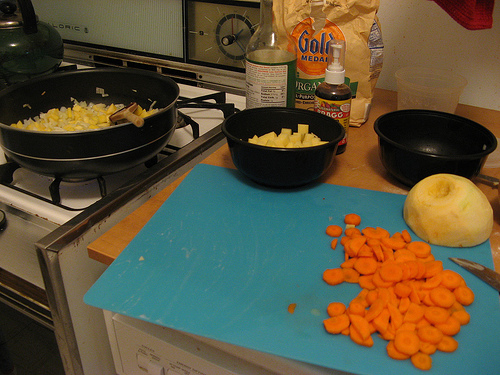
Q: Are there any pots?
A: Yes, there is a pot.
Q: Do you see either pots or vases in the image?
A: Yes, there is a pot.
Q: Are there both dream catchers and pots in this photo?
A: No, there is a pot but no dream catchers.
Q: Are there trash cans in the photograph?
A: No, there are no trash cans.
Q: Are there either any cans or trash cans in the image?
A: No, there are no trash cans or cans.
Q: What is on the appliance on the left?
A: The pot is on the gas stove.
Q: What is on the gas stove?
A: The pot is on the gas stove.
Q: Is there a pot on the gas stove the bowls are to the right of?
A: Yes, there is a pot on the gas stove.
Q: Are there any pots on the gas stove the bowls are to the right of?
A: Yes, there is a pot on the gas stove.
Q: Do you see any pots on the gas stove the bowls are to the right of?
A: Yes, there is a pot on the gas stove.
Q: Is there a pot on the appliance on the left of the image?
A: Yes, there is a pot on the gas stove.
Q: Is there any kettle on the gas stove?
A: No, there is a pot on the gas stove.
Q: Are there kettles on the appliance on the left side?
A: No, there is a pot on the gas stove.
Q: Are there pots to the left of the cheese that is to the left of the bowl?
A: Yes, there is a pot to the left of the cheese.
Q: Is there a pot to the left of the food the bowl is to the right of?
A: Yes, there is a pot to the left of the cheese.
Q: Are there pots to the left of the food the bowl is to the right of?
A: Yes, there is a pot to the left of the cheese.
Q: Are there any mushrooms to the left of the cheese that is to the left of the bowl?
A: No, there is a pot to the left of the cheese.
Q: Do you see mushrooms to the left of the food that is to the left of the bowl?
A: No, there is a pot to the left of the cheese.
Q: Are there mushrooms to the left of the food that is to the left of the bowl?
A: No, there is a pot to the left of the cheese.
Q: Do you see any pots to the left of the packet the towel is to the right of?
A: Yes, there is a pot to the left of the packet.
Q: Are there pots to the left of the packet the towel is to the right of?
A: Yes, there is a pot to the left of the packet.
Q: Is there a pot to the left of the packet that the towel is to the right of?
A: Yes, there is a pot to the left of the packet.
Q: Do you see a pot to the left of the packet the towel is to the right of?
A: Yes, there is a pot to the left of the packet.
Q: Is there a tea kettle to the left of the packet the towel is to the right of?
A: No, there is a pot to the left of the packet.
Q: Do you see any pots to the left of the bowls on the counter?
A: Yes, there is a pot to the left of the bowls.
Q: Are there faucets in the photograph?
A: No, there are no faucets.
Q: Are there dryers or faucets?
A: No, there are no faucets or dryers.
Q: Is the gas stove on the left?
A: Yes, the gas stove is on the left of the image.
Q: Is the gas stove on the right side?
A: No, the gas stove is on the left of the image.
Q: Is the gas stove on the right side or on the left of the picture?
A: The gas stove is on the left of the image.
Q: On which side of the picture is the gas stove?
A: The gas stove is on the left of the image.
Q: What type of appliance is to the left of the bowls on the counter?
A: The appliance is a gas stove.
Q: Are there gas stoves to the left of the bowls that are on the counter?
A: Yes, there is a gas stove to the left of the bowls.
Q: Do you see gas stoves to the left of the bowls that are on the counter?
A: Yes, there is a gas stove to the left of the bowls.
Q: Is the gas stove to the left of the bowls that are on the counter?
A: Yes, the gas stove is to the left of the bowls.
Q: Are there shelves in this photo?
A: No, there are no shelves.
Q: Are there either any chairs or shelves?
A: No, there are no shelves or chairs.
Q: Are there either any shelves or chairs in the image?
A: No, there are no shelves or chairs.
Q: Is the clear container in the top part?
A: Yes, the container is in the top of the image.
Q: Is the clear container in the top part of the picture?
A: Yes, the container is in the top of the image.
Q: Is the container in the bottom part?
A: No, the container is in the top of the image.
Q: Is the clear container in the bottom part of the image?
A: No, the container is in the top of the image.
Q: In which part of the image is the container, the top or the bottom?
A: The container is in the top of the image.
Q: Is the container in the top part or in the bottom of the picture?
A: The container is in the top of the image.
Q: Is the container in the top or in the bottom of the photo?
A: The container is in the top of the image.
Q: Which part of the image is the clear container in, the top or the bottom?
A: The container is in the top of the image.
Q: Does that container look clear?
A: Yes, the container is clear.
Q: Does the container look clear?
A: Yes, the container is clear.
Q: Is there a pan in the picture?
A: Yes, there is a pan.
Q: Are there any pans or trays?
A: Yes, there is a pan.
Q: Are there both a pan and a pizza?
A: No, there is a pan but no pizzas.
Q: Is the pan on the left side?
A: Yes, the pan is on the left of the image.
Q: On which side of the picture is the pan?
A: The pan is on the left of the image.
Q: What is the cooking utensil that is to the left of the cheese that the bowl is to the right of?
A: The cooking utensil is a pan.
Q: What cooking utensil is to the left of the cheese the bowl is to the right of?
A: The cooking utensil is a pan.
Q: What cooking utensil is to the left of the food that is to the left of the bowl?
A: The cooking utensil is a pan.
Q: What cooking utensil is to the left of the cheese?
A: The cooking utensil is a pan.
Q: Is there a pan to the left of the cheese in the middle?
A: Yes, there is a pan to the left of the cheese.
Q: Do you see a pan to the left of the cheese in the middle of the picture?
A: Yes, there is a pan to the left of the cheese.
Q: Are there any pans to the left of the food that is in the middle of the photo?
A: Yes, there is a pan to the left of the cheese.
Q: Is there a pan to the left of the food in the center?
A: Yes, there is a pan to the left of the cheese.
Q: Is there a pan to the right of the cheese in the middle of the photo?
A: No, the pan is to the left of the cheese.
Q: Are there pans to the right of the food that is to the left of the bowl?
A: No, the pan is to the left of the cheese.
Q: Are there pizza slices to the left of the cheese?
A: No, there is a pan to the left of the cheese.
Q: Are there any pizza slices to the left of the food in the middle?
A: No, there is a pan to the left of the cheese.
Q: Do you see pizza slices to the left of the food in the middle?
A: No, there is a pan to the left of the cheese.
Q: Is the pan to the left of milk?
A: No, the pan is to the left of the cheese.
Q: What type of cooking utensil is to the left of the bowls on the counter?
A: The cooking utensil is a pan.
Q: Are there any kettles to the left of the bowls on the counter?
A: No, there is a pan to the left of the bowls.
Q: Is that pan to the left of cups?
A: No, the pan is to the left of the bowls.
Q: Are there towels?
A: Yes, there is a towel.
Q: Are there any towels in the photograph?
A: Yes, there is a towel.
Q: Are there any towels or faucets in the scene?
A: Yes, there is a towel.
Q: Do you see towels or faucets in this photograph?
A: Yes, there is a towel.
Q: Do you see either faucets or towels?
A: Yes, there is a towel.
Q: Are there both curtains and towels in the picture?
A: No, there is a towel but no curtains.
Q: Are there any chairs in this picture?
A: No, there are no chairs.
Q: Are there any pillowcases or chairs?
A: No, there are no chairs or pillowcases.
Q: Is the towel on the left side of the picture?
A: No, the towel is on the right of the image.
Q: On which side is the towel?
A: The towel is on the right of the image.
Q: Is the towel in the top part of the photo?
A: Yes, the towel is in the top of the image.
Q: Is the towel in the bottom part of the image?
A: No, the towel is in the top of the image.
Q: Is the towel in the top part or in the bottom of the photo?
A: The towel is in the top of the image.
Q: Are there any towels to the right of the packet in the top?
A: Yes, there is a towel to the right of the packet.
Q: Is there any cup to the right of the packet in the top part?
A: No, there is a towel to the right of the packet.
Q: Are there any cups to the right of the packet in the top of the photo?
A: No, there is a towel to the right of the packet.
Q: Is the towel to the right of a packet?
A: Yes, the towel is to the right of a packet.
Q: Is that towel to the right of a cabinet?
A: No, the towel is to the right of a packet.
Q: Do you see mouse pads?
A: No, there are no mouse pads.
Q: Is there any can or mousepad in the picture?
A: No, there are no mouse pads or cans.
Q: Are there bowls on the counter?
A: Yes, there are bowls on the counter.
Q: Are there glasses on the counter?
A: No, there are bowls on the counter.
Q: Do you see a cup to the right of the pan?
A: No, there are bowls to the right of the pan.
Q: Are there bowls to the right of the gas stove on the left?
A: Yes, there are bowls to the right of the gas stove.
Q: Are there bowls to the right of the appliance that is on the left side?
A: Yes, there are bowls to the right of the gas stove.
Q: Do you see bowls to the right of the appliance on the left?
A: Yes, there are bowls to the right of the gas stove.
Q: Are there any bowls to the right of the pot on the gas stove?
A: Yes, there are bowls to the right of the pot.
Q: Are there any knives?
A: Yes, there is a knife.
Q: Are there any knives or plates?
A: Yes, there is a knife.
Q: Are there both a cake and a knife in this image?
A: No, there is a knife but no cakes.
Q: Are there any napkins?
A: No, there are no napkins.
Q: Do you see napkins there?
A: No, there are no napkins.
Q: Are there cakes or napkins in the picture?
A: No, there are no napkins or cakes.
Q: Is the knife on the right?
A: Yes, the knife is on the right of the image.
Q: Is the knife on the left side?
A: No, the knife is on the right of the image.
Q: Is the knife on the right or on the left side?
A: The knife is on the right of the image.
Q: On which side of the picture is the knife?
A: The knife is on the right of the image.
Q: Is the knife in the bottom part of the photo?
A: Yes, the knife is in the bottom of the image.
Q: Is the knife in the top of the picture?
A: No, the knife is in the bottom of the image.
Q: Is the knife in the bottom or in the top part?
A: The knife is in the bottom of the image.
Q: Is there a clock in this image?
A: No, there are no clocks.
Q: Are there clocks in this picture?
A: No, there are no clocks.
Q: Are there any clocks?
A: No, there are no clocks.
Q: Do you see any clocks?
A: No, there are no clocks.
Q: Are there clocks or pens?
A: No, there are no clocks or pens.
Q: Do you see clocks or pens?
A: No, there are no clocks or pens.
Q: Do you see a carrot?
A: Yes, there are carrots.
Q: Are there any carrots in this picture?
A: Yes, there are carrots.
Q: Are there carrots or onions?
A: Yes, there are carrots.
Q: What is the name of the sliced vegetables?
A: The vegetables are carrots.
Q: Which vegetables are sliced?
A: The vegetables are carrots.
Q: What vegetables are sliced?
A: The vegetables are carrots.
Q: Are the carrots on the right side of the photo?
A: Yes, the carrots are on the right of the image.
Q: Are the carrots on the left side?
A: No, the carrots are on the right of the image.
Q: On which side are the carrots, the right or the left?
A: The carrots are on the right of the image.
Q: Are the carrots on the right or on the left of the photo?
A: The carrots are on the right of the image.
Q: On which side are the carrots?
A: The carrots are on the right of the image.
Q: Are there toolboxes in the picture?
A: No, there are no toolboxes.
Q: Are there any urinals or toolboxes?
A: No, there are no toolboxes or urinals.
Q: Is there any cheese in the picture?
A: Yes, there is cheese.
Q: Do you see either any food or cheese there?
A: Yes, there is cheese.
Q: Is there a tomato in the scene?
A: No, there are no tomatoes.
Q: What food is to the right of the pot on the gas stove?
A: The food is cheese.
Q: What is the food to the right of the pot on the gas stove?
A: The food is cheese.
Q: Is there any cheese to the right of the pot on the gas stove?
A: Yes, there is cheese to the right of the pot.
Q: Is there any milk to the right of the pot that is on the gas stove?
A: No, there is cheese to the right of the pot.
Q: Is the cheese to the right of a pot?
A: Yes, the cheese is to the right of a pot.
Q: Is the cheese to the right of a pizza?
A: No, the cheese is to the right of a pot.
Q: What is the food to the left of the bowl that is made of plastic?
A: The food is cheese.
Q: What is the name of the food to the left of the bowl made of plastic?
A: The food is cheese.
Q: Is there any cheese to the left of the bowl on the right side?
A: Yes, there is cheese to the left of the bowl.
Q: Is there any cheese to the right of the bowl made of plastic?
A: No, the cheese is to the left of the bowl.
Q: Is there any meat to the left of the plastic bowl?
A: No, there is cheese to the left of the bowl.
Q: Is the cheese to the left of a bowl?
A: Yes, the cheese is to the left of a bowl.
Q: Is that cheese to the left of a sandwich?
A: No, the cheese is to the left of a bowl.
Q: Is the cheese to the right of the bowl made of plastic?
A: No, the cheese is to the left of the bowl.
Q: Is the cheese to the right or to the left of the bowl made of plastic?
A: The cheese is to the left of the bowl.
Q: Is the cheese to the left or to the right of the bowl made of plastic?
A: The cheese is to the left of the bowl.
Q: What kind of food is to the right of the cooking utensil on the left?
A: The food is cheese.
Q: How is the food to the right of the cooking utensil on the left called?
A: The food is cheese.